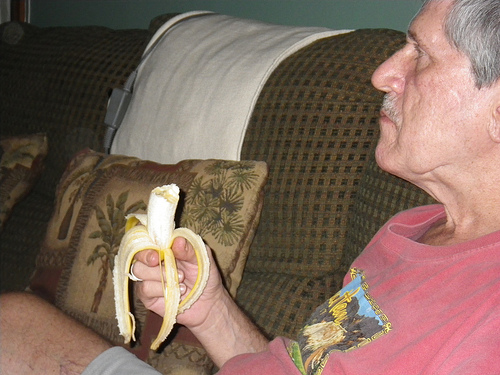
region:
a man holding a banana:
[107, 1, 494, 357]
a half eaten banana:
[110, 155, 216, 300]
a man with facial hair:
[346, 15, 493, 187]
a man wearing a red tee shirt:
[303, 9, 492, 364]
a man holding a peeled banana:
[68, 65, 485, 370]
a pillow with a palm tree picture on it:
[0, 143, 287, 295]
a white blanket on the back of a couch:
[58, 13, 360, 198]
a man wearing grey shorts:
[60, 0, 486, 370]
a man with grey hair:
[356, 3, 496, 200]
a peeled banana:
[90, 150, 240, 352]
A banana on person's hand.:
[114, 183, 210, 351]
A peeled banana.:
[112, 179, 212, 348]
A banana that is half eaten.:
[109, 183, 210, 349]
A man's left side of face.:
[367, 0, 495, 237]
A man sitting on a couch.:
[8, 3, 495, 373]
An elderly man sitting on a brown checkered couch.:
[0, 3, 497, 372]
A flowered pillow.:
[26, 145, 274, 346]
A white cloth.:
[108, 10, 353, 159]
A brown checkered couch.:
[2, 7, 452, 370]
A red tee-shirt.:
[211, 193, 492, 373]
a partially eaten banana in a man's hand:
[104, 164, 236, 370]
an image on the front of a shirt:
[285, 280, 394, 364]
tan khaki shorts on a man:
[90, 354, 152, 367]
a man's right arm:
[177, 241, 272, 361]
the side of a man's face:
[376, 5, 498, 245]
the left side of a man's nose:
[371, 60, 402, 98]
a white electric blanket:
[144, 22, 281, 153]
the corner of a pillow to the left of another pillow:
[8, 133, 48, 194]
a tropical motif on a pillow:
[76, 157, 126, 304]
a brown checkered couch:
[282, 103, 355, 248]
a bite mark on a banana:
[150, 182, 180, 207]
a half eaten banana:
[147, 186, 178, 238]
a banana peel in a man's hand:
[119, 217, 215, 334]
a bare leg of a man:
[7, 291, 122, 372]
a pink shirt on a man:
[419, 253, 492, 345]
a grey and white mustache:
[381, 91, 404, 126]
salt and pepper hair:
[454, 3, 496, 58]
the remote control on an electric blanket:
[97, 91, 125, 124]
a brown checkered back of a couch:
[281, 88, 343, 218]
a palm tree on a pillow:
[82, 191, 119, 306]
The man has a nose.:
[368, 36, 411, 93]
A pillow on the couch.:
[46, 130, 266, 356]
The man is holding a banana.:
[102, 172, 225, 348]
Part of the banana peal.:
[140, 235, 190, 355]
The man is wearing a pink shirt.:
[210, 177, 499, 372]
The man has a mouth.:
[375, 102, 415, 133]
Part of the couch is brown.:
[292, 101, 359, 227]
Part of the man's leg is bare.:
[2, 318, 67, 371]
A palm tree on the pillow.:
[72, 181, 145, 317]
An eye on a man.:
[406, 39, 433, 72]